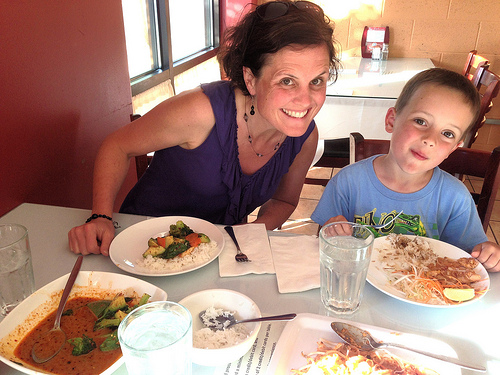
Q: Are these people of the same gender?
A: No, they are both male and female.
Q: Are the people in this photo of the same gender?
A: No, they are both male and female.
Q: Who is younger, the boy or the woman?
A: The boy is younger than the woman.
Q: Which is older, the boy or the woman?
A: The woman is older than the boy.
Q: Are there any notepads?
A: No, there are no notepads.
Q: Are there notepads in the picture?
A: No, there are no notepads.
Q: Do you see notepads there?
A: No, there are no notepads.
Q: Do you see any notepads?
A: No, there are no notepads.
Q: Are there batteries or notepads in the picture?
A: No, there are no notepads or batteries.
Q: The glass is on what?
A: The glass is on the table.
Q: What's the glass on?
A: The glass is on the table.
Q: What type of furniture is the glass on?
A: The glass is on the table.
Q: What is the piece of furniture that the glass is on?
A: The piece of furniture is a table.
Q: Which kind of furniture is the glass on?
A: The glass is on the table.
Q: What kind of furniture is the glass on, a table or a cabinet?
A: The glass is on a table.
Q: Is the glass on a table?
A: Yes, the glass is on a table.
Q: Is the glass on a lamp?
A: No, the glass is on a table.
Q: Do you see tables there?
A: Yes, there is a table.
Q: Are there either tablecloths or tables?
A: Yes, there is a table.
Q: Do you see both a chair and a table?
A: Yes, there are both a table and a chair.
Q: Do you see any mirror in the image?
A: No, there are no mirrors.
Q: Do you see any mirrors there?
A: No, there are no mirrors.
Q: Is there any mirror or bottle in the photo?
A: No, there are no mirrors or bottles.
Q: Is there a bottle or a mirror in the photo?
A: No, there are no mirrors or bottles.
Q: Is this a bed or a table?
A: This is a table.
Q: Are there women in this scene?
A: Yes, there is a woman.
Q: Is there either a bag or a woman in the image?
A: Yes, there is a woman.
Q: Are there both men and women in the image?
A: No, there is a woman but no men.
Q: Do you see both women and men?
A: No, there is a woman but no men.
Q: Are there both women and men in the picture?
A: No, there is a woman but no men.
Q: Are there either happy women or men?
A: Yes, there is a happy woman.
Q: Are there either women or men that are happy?
A: Yes, the woman is happy.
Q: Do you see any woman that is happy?
A: Yes, there is a happy woman.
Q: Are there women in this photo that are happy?
A: Yes, there is a woman that is happy.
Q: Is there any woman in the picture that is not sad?
A: Yes, there is a happy woman.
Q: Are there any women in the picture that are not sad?
A: Yes, there is a happy woman.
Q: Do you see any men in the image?
A: No, there are no men.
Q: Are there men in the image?
A: No, there are no men.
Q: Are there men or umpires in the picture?
A: No, there are no men or umpires.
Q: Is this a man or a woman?
A: This is a woman.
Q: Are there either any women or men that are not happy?
A: No, there is a woman but she is happy.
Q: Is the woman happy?
A: Yes, the woman is happy.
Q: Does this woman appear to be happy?
A: Yes, the woman is happy.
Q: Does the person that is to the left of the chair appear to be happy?
A: Yes, the woman is happy.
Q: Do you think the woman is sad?
A: No, the woman is happy.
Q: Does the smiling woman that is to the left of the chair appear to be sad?
A: No, the woman is happy.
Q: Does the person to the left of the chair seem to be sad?
A: No, the woman is happy.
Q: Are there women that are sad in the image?
A: No, there is a woman but she is happy.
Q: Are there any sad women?
A: No, there is a woman but she is happy.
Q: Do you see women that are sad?
A: No, there is a woman but she is happy.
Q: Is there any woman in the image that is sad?
A: No, there is a woman but she is happy.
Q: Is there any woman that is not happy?
A: No, there is a woman but she is happy.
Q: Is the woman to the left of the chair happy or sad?
A: The woman is happy.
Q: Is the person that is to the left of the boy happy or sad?
A: The woman is happy.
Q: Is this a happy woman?
A: Yes, this is a happy woman.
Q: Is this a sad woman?
A: No, this is a happy woman.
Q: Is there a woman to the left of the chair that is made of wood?
A: Yes, there is a woman to the left of the chair.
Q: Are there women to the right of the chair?
A: No, the woman is to the left of the chair.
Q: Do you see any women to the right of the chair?
A: No, the woman is to the left of the chair.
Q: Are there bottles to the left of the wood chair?
A: No, there is a woman to the left of the chair.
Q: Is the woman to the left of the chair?
A: Yes, the woman is to the left of the chair.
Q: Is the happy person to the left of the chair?
A: Yes, the woman is to the left of the chair.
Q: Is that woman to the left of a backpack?
A: No, the woman is to the left of the chair.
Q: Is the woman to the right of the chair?
A: No, the woman is to the left of the chair.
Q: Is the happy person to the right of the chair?
A: No, the woman is to the left of the chair.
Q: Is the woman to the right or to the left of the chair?
A: The woman is to the left of the chair.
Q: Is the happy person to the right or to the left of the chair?
A: The woman is to the left of the chair.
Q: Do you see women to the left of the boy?
A: Yes, there is a woman to the left of the boy.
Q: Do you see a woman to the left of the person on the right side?
A: Yes, there is a woman to the left of the boy.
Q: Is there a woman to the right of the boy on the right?
A: No, the woman is to the left of the boy.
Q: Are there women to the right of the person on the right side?
A: No, the woman is to the left of the boy.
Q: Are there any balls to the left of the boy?
A: No, there is a woman to the left of the boy.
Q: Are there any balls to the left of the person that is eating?
A: No, there is a woman to the left of the boy.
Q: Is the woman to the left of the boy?
A: Yes, the woman is to the left of the boy.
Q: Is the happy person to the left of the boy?
A: Yes, the woman is to the left of the boy.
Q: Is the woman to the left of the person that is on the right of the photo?
A: Yes, the woman is to the left of the boy.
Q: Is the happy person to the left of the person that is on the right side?
A: Yes, the woman is to the left of the boy.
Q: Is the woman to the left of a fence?
A: No, the woman is to the left of the boy.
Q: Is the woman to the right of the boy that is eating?
A: No, the woman is to the left of the boy.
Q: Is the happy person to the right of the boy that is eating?
A: No, the woman is to the left of the boy.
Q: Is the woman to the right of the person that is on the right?
A: No, the woman is to the left of the boy.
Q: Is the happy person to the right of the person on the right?
A: No, the woman is to the left of the boy.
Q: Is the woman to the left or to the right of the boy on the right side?
A: The woman is to the left of the boy.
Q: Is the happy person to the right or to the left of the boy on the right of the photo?
A: The woman is to the left of the boy.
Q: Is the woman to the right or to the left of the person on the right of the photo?
A: The woman is to the left of the boy.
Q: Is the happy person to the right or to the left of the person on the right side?
A: The woman is to the left of the boy.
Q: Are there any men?
A: No, there are no men.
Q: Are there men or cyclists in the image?
A: No, there are no men or cyclists.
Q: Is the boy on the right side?
A: Yes, the boy is on the right of the image.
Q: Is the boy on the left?
A: No, the boy is on the right of the image.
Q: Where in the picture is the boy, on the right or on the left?
A: The boy is on the right of the image.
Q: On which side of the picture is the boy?
A: The boy is on the right of the image.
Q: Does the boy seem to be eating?
A: Yes, the boy is eating.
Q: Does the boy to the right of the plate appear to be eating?
A: Yes, the boy is eating.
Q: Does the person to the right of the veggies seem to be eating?
A: Yes, the boy is eating.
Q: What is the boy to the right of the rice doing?
A: The boy is eating.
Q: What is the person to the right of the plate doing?
A: The boy is eating.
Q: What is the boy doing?
A: The boy is eating.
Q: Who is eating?
A: The boy is eating.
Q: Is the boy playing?
A: No, the boy is eating.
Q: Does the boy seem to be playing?
A: No, the boy is eating.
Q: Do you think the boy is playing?
A: No, the boy is eating.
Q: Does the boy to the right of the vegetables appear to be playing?
A: No, the boy is eating.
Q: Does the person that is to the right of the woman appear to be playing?
A: No, the boy is eating.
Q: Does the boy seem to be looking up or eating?
A: The boy is eating.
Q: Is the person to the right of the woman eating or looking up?
A: The boy is eating.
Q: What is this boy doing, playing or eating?
A: The boy is eating.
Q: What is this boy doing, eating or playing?
A: The boy is eating.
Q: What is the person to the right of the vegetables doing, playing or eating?
A: The boy is eating.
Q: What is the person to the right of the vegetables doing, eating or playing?
A: The boy is eating.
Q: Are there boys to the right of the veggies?
A: Yes, there is a boy to the right of the veggies.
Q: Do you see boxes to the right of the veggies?
A: No, there is a boy to the right of the veggies.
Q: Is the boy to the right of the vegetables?
A: Yes, the boy is to the right of the vegetables.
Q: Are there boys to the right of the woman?
A: Yes, there is a boy to the right of the woman.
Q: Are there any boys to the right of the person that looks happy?
A: Yes, there is a boy to the right of the woman.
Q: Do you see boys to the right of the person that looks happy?
A: Yes, there is a boy to the right of the woman.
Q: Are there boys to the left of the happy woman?
A: No, the boy is to the right of the woman.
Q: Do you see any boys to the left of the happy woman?
A: No, the boy is to the right of the woman.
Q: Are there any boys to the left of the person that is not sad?
A: No, the boy is to the right of the woman.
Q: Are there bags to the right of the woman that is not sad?
A: No, there is a boy to the right of the woman.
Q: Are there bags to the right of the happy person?
A: No, there is a boy to the right of the woman.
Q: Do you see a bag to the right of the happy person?
A: No, there is a boy to the right of the woman.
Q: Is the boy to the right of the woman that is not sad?
A: Yes, the boy is to the right of the woman.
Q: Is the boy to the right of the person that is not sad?
A: Yes, the boy is to the right of the woman.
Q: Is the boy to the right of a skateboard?
A: No, the boy is to the right of the woman.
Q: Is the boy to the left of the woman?
A: No, the boy is to the right of the woman.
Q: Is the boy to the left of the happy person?
A: No, the boy is to the right of the woman.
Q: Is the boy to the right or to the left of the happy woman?
A: The boy is to the right of the woman.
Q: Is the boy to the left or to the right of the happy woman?
A: The boy is to the right of the woman.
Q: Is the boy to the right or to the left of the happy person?
A: The boy is to the right of the woman.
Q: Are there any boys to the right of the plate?
A: Yes, there is a boy to the right of the plate.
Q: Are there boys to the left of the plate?
A: No, the boy is to the right of the plate.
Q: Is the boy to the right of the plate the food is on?
A: Yes, the boy is to the right of the plate.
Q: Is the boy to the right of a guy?
A: No, the boy is to the right of the plate.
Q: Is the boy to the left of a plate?
A: No, the boy is to the right of a plate.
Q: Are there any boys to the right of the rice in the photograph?
A: Yes, there is a boy to the right of the rice.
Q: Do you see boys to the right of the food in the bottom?
A: Yes, there is a boy to the right of the rice.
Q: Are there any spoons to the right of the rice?
A: No, there is a boy to the right of the rice.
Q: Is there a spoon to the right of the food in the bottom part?
A: No, there is a boy to the right of the rice.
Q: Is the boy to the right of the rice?
A: Yes, the boy is to the right of the rice.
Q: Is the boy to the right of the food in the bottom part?
A: Yes, the boy is to the right of the rice.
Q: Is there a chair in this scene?
A: Yes, there is a chair.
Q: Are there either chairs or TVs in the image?
A: Yes, there is a chair.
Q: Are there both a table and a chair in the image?
A: Yes, there are both a chair and a table.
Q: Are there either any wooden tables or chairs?
A: Yes, there is a wood chair.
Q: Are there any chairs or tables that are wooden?
A: Yes, the chair is wooden.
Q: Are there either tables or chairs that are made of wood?
A: Yes, the chair is made of wood.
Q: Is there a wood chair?
A: Yes, there is a chair that is made of wood.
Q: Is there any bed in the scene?
A: No, there are no beds.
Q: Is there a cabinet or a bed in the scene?
A: No, there are no beds or cabinets.